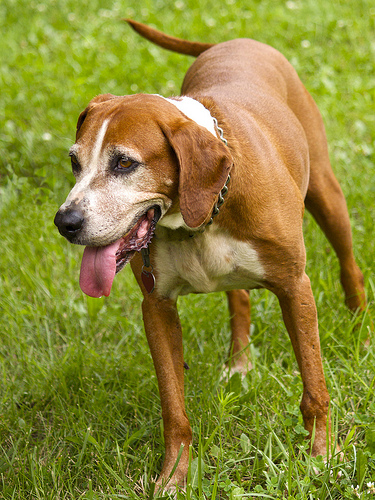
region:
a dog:
[23, 20, 373, 484]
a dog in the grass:
[36, 16, 374, 498]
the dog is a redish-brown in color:
[54, 61, 370, 495]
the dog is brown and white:
[29, 18, 371, 499]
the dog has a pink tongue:
[37, 23, 373, 499]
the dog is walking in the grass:
[24, 24, 373, 488]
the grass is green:
[2, 182, 346, 495]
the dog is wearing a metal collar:
[34, 30, 374, 497]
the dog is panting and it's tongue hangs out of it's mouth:
[53, 20, 373, 482]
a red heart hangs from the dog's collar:
[28, 15, 299, 485]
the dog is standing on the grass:
[55, 15, 360, 481]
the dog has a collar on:
[160, 97, 231, 236]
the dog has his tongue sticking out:
[79, 232, 119, 298]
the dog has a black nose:
[55, 206, 85, 237]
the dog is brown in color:
[55, 17, 361, 492]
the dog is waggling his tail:
[122, 17, 220, 61]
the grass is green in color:
[2, 1, 373, 498]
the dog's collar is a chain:
[163, 103, 234, 231]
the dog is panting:
[56, 199, 164, 293]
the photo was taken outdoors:
[0, 1, 371, 496]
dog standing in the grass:
[63, 95, 356, 496]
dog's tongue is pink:
[71, 245, 121, 305]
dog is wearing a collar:
[161, 91, 236, 259]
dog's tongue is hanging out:
[61, 129, 210, 333]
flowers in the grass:
[317, 470, 371, 497]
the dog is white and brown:
[163, 216, 292, 319]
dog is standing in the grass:
[81, 76, 368, 496]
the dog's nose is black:
[43, 206, 103, 245]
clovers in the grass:
[199, 396, 335, 498]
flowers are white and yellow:
[315, 472, 373, 497]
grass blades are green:
[36, 334, 272, 484]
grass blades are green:
[9, 309, 172, 497]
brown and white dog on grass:
[58, 15, 361, 439]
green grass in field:
[15, 364, 139, 474]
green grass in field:
[210, 383, 293, 486]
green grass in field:
[14, 10, 120, 81]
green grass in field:
[290, 13, 362, 56]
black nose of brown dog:
[54, 200, 85, 237]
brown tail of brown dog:
[111, 6, 216, 65]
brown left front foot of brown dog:
[295, 386, 358, 476]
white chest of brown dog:
[152, 240, 291, 296]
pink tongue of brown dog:
[80, 234, 125, 315]